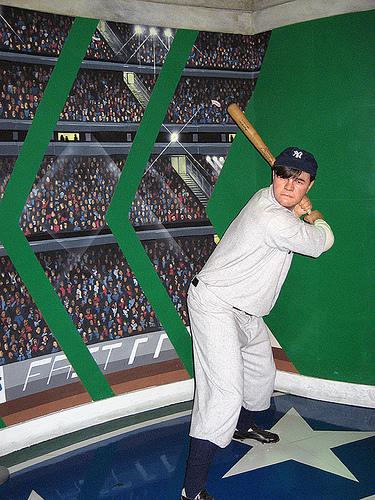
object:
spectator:
[82, 290, 88, 305]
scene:
[0, 0, 373, 500]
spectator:
[68, 210, 75, 224]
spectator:
[112, 264, 119, 280]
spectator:
[177, 192, 182, 203]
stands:
[0, 224, 220, 406]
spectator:
[106, 313, 115, 327]